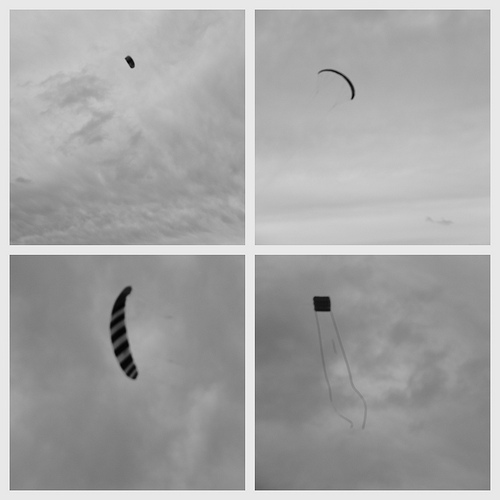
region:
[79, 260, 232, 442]
a parasail in the air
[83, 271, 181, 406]
a parasail in the iar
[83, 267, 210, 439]
a parasail in the gray sky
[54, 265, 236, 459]
a parasail high in the air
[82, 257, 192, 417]
a parasail high in the sky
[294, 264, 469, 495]
a kite in the air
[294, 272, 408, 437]
a kite in the sky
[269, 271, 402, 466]
a square kite in the air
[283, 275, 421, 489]
a kite with a tail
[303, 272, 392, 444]
a kite flying high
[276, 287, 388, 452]
square black kite with string hanging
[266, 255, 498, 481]
sky is full of swirling dark clouds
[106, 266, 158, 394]
crescent kite black and light brown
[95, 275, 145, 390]
crescent kite flying in sky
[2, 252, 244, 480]
sky is dark with white clouds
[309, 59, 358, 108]
crescent shaped kite is facing a different direction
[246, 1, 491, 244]
crescent kite is flying high in cloudy sky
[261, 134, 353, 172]
bird is flying in the sky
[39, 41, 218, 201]
small blob of a kite among white swirling clouds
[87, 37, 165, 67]
kite is far away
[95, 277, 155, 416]
large kite has stripes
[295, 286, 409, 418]
square kite has tail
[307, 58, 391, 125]
large kite has curve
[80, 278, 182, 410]
striped kite in grey sky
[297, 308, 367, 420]
square kite has long stringy tail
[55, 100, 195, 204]
sky has many clouds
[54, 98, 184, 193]
clouds in sky are thick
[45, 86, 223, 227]
overcast and dreary sky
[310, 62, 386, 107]
kite has curves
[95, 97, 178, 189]
the sky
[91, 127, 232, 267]
the sky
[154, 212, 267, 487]
the sky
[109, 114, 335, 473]
the sky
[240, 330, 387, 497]
the sky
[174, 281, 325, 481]
the sky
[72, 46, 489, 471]
four kites in sky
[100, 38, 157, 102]
kite is small and dark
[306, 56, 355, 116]
kite is large and curved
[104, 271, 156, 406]
kite is large and striped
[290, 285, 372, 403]
kite is small and square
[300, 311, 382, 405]
kite has long tail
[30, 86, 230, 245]
sky has many clouds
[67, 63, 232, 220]
clouds are white and thick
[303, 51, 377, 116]
kite curved in sky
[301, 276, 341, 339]
square kite in sky